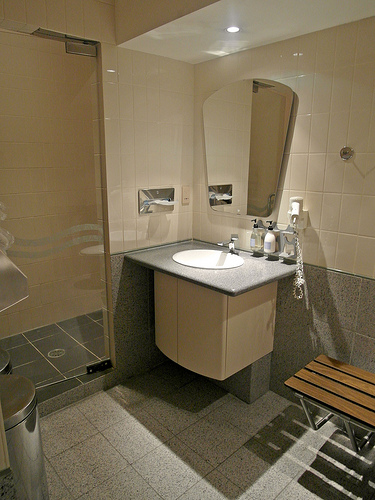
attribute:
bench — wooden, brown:
[283, 353, 374, 430]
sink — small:
[172, 249, 245, 271]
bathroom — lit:
[1, 0, 374, 499]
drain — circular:
[47, 346, 67, 360]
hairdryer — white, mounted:
[286, 196, 311, 310]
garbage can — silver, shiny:
[0, 374, 50, 499]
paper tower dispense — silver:
[138, 188, 177, 215]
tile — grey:
[39, 360, 373, 498]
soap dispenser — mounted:
[249, 217, 261, 251]